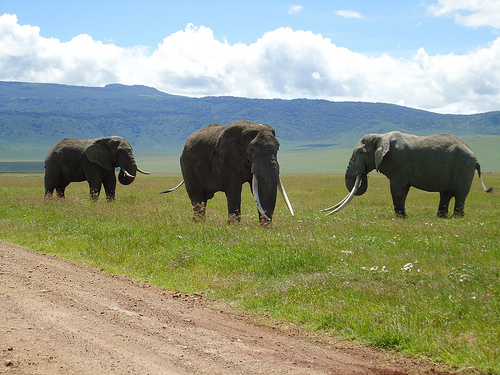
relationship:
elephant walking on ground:
[43, 133, 151, 202] [1, 171, 500, 373]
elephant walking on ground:
[160, 118, 296, 226] [1, 171, 500, 373]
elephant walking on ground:
[319, 131, 494, 221] [1, 171, 500, 373]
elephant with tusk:
[43, 133, 151, 202] [121, 168, 136, 180]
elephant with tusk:
[43, 133, 151, 202] [136, 168, 150, 176]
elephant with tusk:
[160, 118, 296, 226] [250, 174, 272, 222]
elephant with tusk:
[160, 118, 296, 226] [276, 173, 295, 218]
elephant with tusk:
[319, 131, 494, 221] [323, 175, 361, 216]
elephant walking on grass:
[43, 133, 151, 202] [0, 172, 499, 374]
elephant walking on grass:
[160, 118, 296, 226] [0, 172, 499, 374]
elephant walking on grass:
[319, 131, 494, 221] [0, 172, 499, 374]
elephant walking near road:
[43, 133, 151, 202] [0, 239, 438, 374]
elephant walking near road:
[160, 118, 296, 226] [0, 239, 438, 374]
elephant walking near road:
[319, 131, 494, 221] [0, 239, 438, 374]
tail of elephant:
[158, 174, 186, 194] [160, 118, 296, 226]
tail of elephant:
[474, 162, 495, 194] [319, 131, 494, 221]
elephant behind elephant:
[43, 133, 151, 202] [160, 118, 296, 226]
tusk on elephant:
[323, 175, 361, 216] [319, 131, 494, 221]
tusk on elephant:
[276, 173, 295, 218] [160, 118, 296, 226]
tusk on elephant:
[250, 174, 272, 222] [160, 118, 296, 226]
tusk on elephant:
[121, 168, 136, 180] [43, 133, 151, 202]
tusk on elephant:
[136, 168, 150, 176] [43, 133, 151, 202]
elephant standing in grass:
[43, 133, 151, 202] [0, 172, 499, 374]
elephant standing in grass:
[160, 118, 296, 226] [0, 172, 499, 374]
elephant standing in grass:
[319, 131, 494, 221] [0, 172, 499, 374]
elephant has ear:
[43, 133, 151, 202] [81, 141, 117, 173]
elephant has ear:
[160, 118, 296, 226] [210, 124, 247, 189]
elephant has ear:
[319, 131, 494, 221] [374, 133, 390, 175]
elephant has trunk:
[43, 133, 151, 202] [117, 154, 137, 186]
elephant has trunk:
[160, 118, 296, 226] [250, 157, 282, 225]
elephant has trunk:
[319, 131, 494, 221] [345, 151, 369, 198]